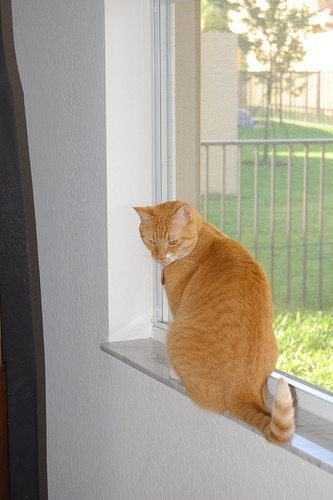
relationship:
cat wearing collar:
[127, 190, 303, 447] [158, 267, 167, 286]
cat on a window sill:
[127, 190, 303, 447] [101, 337, 332, 471]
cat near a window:
[127, 190, 303, 447] [172, 0, 331, 395]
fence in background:
[239, 69, 332, 123] [202, 0, 331, 210]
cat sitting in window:
[130, 199, 295, 446] [150, 0, 332, 422]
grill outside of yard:
[236, 106, 260, 141] [198, 116, 332, 394]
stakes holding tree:
[244, 115, 311, 176] [238, 9, 311, 159]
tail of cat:
[258, 374, 296, 451] [127, 190, 303, 447]